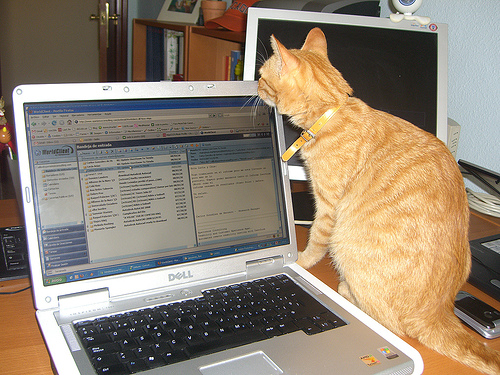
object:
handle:
[89, 12, 123, 26]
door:
[0, 0, 107, 109]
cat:
[244, 25, 499, 375]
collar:
[280, 102, 341, 163]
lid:
[10, 81, 299, 303]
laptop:
[15, 81, 424, 375]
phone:
[447, 291, 500, 338]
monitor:
[242, 7, 439, 183]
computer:
[243, 4, 449, 229]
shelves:
[131, 19, 190, 82]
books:
[165, 29, 177, 77]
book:
[226, 49, 244, 80]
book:
[143, 25, 162, 82]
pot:
[201, 1, 226, 30]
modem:
[446, 119, 460, 162]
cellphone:
[450, 293, 500, 341]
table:
[0, 154, 500, 375]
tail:
[417, 318, 500, 374]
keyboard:
[77, 274, 345, 375]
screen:
[19, 95, 288, 283]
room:
[1, 1, 500, 375]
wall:
[435, 0, 499, 169]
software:
[27, 98, 294, 281]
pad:
[207, 349, 272, 373]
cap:
[204, 0, 264, 32]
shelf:
[140, 11, 272, 87]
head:
[253, 27, 347, 116]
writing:
[169, 271, 193, 281]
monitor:
[23, 92, 287, 285]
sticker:
[360, 354, 380, 367]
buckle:
[301, 130, 314, 141]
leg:
[294, 206, 340, 268]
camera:
[388, 0, 432, 24]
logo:
[377, 345, 399, 359]